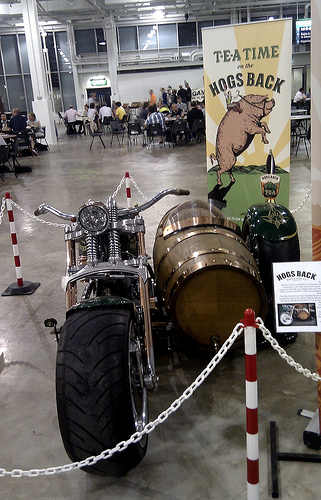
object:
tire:
[55, 309, 150, 478]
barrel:
[154, 197, 268, 352]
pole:
[242, 305, 261, 499]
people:
[99, 102, 115, 136]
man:
[224, 85, 243, 113]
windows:
[59, 70, 77, 111]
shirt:
[116, 105, 126, 120]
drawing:
[209, 88, 277, 189]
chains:
[87, 456, 97, 466]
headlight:
[78, 202, 110, 232]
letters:
[213, 49, 221, 63]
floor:
[55, 145, 164, 174]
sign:
[271, 258, 320, 335]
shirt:
[151, 93, 157, 105]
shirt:
[145, 112, 166, 132]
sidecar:
[153, 193, 264, 353]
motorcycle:
[34, 188, 189, 482]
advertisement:
[202, 19, 293, 172]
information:
[276, 270, 321, 327]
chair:
[144, 122, 165, 149]